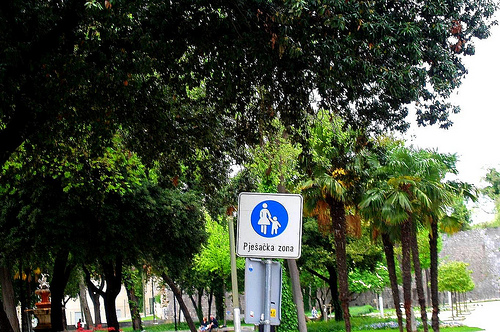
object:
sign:
[234, 190, 306, 259]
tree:
[356, 131, 421, 330]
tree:
[389, 146, 448, 330]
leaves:
[0, 0, 500, 294]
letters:
[241, 240, 251, 253]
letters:
[269, 243, 276, 250]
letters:
[246, 242, 251, 254]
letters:
[273, 242, 283, 252]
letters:
[288, 244, 296, 252]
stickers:
[248, 310, 261, 321]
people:
[200, 314, 217, 330]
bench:
[196, 324, 256, 330]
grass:
[81, 304, 489, 330]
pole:
[249, 257, 290, 329]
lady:
[256, 202, 271, 234]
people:
[175, 308, 238, 330]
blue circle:
[249, 197, 288, 237]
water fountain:
[29, 272, 60, 327]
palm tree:
[413, 145, 472, 328]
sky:
[409, 1, 499, 177]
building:
[144, 275, 243, 322]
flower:
[77, 321, 82, 329]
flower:
[94, 321, 98, 330]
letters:
[253, 242, 270, 254]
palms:
[357, 133, 408, 332]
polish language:
[239, 242, 296, 256]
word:
[242, 241, 274, 254]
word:
[278, 242, 295, 254]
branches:
[2, 4, 499, 331]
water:
[470, 303, 499, 325]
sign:
[246, 257, 281, 322]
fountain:
[34, 274, 54, 330]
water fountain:
[23, 284, 54, 331]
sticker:
[245, 263, 254, 274]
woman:
[311, 305, 318, 317]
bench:
[306, 315, 323, 320]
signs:
[229, 190, 301, 328]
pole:
[222, 210, 243, 330]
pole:
[286, 260, 308, 330]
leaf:
[353, 42, 359, 49]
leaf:
[303, 10, 326, 35]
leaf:
[214, 102, 219, 109]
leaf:
[144, 47, 163, 71]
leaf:
[109, 200, 113, 205]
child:
[269, 215, 281, 237]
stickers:
[264, 300, 276, 322]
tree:
[0, 0, 499, 332]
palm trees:
[295, 103, 373, 323]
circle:
[249, 198, 289, 239]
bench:
[143, 297, 219, 332]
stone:
[363, 303, 489, 332]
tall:
[322, 163, 433, 332]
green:
[92, 85, 481, 252]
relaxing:
[183, 309, 224, 332]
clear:
[298, 280, 444, 332]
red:
[59, 301, 125, 332]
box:
[225, 257, 302, 332]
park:
[0, 93, 492, 332]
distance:
[0, 0, 500, 332]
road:
[388, 297, 500, 331]